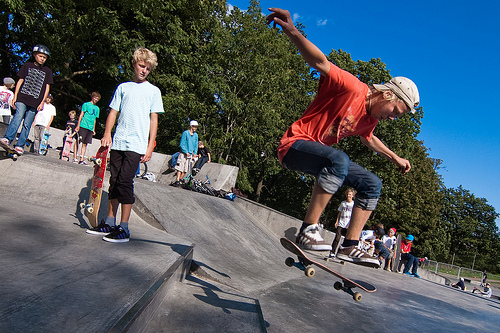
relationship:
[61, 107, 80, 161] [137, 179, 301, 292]
boy on ramp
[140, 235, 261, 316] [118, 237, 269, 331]
shadow on steps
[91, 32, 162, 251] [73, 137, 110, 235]
boy holding skateboard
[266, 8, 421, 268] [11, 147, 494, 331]
boy at skate park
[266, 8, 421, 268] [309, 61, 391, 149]
boy wearing shirt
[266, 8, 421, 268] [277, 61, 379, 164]
boy wearing shirt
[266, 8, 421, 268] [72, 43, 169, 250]
boy watching boy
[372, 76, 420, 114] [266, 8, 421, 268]
cap worn by boy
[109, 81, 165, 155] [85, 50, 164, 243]
blue shirt worn by boy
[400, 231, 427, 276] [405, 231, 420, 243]
man wearing cap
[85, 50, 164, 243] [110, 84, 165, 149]
boy in blue shirt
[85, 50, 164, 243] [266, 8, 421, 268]
boy watching boy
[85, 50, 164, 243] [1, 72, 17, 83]
boy in hat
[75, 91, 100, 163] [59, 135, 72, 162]
boy holding skateboard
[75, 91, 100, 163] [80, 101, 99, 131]
boy in shirt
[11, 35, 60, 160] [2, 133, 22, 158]
girl in red shoes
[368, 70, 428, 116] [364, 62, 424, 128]
cap on head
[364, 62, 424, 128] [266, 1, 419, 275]
head on boy